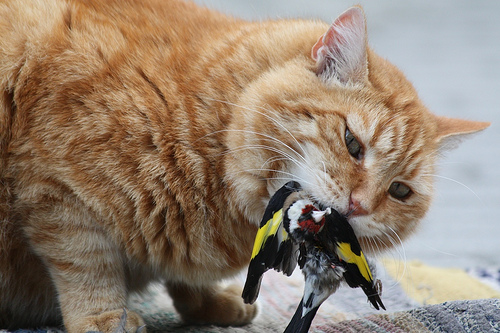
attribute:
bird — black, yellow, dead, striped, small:
[236, 180, 383, 332]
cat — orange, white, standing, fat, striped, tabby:
[5, 2, 492, 332]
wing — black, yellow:
[238, 186, 290, 307]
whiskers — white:
[195, 86, 344, 209]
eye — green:
[343, 123, 366, 163]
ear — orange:
[301, 6, 369, 86]